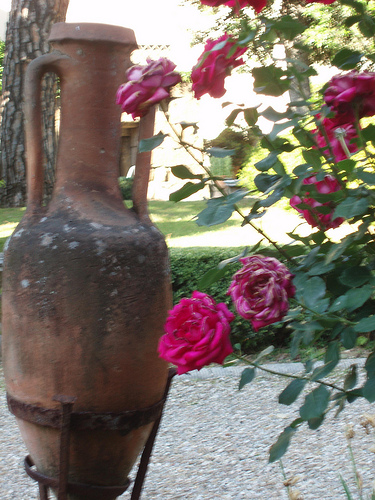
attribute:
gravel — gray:
[5, 338, 374, 498]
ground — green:
[6, 186, 362, 492]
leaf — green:
[299, 249, 369, 326]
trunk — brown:
[2, 1, 58, 205]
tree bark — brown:
[5, 12, 35, 193]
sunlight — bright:
[144, 11, 318, 242]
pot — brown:
[0, 19, 174, 499]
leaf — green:
[291, 268, 338, 318]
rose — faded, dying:
[230, 246, 309, 322]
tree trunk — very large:
[0, 3, 26, 213]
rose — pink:
[157, 290, 233, 374]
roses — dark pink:
[113, 0, 373, 375]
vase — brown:
[0, 21, 174, 498]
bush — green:
[140, 237, 369, 367]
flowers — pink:
[173, 9, 352, 358]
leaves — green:
[200, 183, 250, 228]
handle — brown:
[11, 46, 61, 230]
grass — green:
[152, 200, 225, 247]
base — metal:
[16, 391, 186, 484]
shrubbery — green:
[299, 272, 374, 402]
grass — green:
[174, 209, 237, 237]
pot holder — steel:
[5, 365, 201, 498]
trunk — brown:
[0, 0, 73, 210]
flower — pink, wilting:
[101, 48, 195, 128]